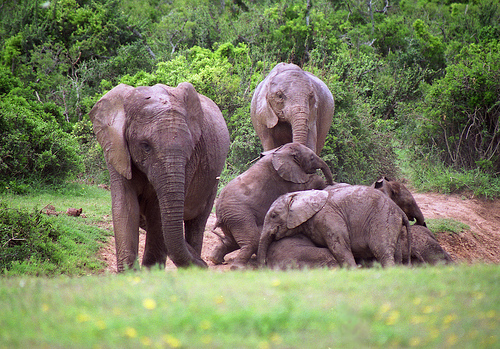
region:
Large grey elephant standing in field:
[90, 76, 219, 262]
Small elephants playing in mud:
[211, 133, 393, 265]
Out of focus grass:
[124, 272, 240, 332]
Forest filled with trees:
[338, 8, 463, 137]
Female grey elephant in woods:
[240, 46, 344, 193]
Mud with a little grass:
[424, 189, 494, 252]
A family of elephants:
[81, 39, 449, 302]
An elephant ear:
[73, 80, 140, 178]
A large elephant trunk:
[136, 149, 213, 274]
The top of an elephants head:
[244, 49, 321, 91]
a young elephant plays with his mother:
[257, 182, 412, 272]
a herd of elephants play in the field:
[0, 0, 497, 347]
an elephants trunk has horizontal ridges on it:
[143, 153, 198, 270]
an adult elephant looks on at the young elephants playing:
[250, 61, 334, 153]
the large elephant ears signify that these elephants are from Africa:
[87, 81, 132, 181]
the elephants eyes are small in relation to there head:
[274, 88, 286, 99]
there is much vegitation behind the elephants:
[0, 0, 497, 189]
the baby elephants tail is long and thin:
[401, 212, 413, 264]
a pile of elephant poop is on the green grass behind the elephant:
[65, 207, 82, 217]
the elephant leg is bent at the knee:
[207, 233, 239, 265]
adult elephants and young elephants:
[80, 40, 455, 290]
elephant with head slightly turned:
[80, 65, 245, 281]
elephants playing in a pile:
[205, 135, 460, 275]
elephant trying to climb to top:
[212, 135, 337, 275]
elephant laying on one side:
[245, 185, 422, 266]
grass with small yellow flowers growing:
[75, 275, 445, 326]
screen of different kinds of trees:
[45, 10, 472, 105]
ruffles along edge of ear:
[72, 90, 127, 185]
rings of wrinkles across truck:
[150, 155, 190, 255]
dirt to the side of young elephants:
[386, 182, 493, 260]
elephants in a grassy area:
[42, 31, 470, 311]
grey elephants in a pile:
[219, 149, 443, 274]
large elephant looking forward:
[84, 77, 221, 281]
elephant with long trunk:
[115, 85, 218, 292]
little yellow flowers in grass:
[353, 292, 442, 339]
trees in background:
[382, 41, 484, 172]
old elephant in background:
[230, 58, 341, 164]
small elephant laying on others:
[255, 175, 419, 280]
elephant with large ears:
[83, 52, 214, 274]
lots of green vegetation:
[0, 35, 101, 295]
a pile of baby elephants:
[212, 141, 450, 302]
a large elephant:
[81, 70, 232, 291]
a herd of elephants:
[61, 43, 458, 299]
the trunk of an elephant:
[144, 160, 211, 274]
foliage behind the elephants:
[419, 30, 499, 205]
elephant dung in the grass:
[36, 200, 89, 223]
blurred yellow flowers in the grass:
[374, 291, 476, 340]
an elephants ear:
[85, 80, 137, 182]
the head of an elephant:
[246, 47, 336, 138]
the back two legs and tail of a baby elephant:
[204, 192, 256, 270]